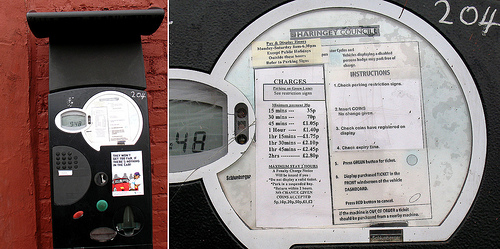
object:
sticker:
[106, 149, 141, 195]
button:
[95, 200, 109, 211]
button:
[72, 210, 85, 219]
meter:
[0, 0, 497, 246]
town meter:
[49, 82, 149, 249]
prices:
[262, 100, 324, 166]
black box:
[48, 33, 157, 249]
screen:
[165, 78, 230, 158]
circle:
[405, 154, 420, 166]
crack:
[166, 117, 262, 204]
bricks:
[2, 0, 166, 249]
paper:
[254, 37, 423, 220]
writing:
[267, 162, 316, 170]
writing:
[271, 199, 315, 205]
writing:
[341, 171, 400, 179]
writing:
[332, 80, 404, 89]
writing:
[344, 66, 394, 77]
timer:
[57, 111, 90, 128]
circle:
[49, 85, 148, 154]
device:
[0, 0, 257, 249]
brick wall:
[1, 1, 56, 249]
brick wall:
[143, 34, 170, 249]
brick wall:
[0, 0, 171, 12]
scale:
[201, 36, 432, 225]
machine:
[27, 9, 161, 249]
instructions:
[320, 42, 436, 222]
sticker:
[74, 91, 143, 149]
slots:
[81, 197, 151, 240]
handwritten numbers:
[429, 0, 500, 36]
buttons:
[54, 150, 79, 169]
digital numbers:
[162, 121, 217, 156]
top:
[21, 6, 164, 27]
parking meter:
[24, 10, 166, 247]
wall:
[0, 0, 171, 249]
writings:
[336, 144, 381, 151]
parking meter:
[171, 1, 484, 249]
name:
[290, 25, 378, 37]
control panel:
[49, 147, 93, 206]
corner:
[391, 0, 500, 64]